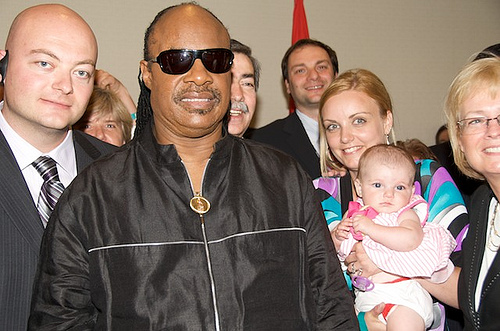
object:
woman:
[445, 49, 500, 331]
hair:
[441, 51, 499, 180]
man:
[25, 1, 358, 331]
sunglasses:
[144, 48, 234, 75]